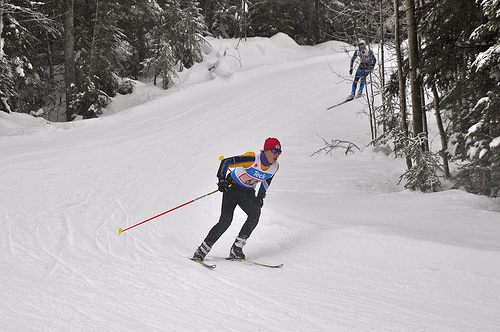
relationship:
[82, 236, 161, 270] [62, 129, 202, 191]
marks on snow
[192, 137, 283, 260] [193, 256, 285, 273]
man on skis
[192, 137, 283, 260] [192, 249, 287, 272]
man on skis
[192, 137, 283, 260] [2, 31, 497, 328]
man on snow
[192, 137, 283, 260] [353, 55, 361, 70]
man on ski pole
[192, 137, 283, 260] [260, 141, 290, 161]
man wearing sunglasses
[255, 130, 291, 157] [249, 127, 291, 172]
cap on head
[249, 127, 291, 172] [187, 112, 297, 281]
head of person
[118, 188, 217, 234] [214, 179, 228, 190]
pole in hand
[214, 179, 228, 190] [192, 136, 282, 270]
hand of person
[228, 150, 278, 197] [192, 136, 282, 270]
racing vest on person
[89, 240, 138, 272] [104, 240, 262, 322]
track in snow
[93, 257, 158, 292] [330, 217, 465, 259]
track in snow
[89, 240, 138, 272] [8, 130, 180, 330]
track in snow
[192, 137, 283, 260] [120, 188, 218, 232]
man holding pole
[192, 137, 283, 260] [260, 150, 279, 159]
man wearing goggles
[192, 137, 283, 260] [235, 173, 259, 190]
man wears number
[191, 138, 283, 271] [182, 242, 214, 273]
man wears skis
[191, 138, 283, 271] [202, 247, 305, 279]
man wears skis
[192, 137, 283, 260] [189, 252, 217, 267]
man wears ski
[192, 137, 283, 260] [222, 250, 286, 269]
man wears ski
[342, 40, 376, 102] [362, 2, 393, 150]
man through trees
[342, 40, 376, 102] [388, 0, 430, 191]
man through trees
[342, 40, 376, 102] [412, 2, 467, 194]
man through trees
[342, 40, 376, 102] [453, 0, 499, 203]
man through trees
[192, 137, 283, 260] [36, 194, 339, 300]
man on slope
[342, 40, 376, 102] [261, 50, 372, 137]
man on slope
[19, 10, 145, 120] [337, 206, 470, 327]
tree near ski trail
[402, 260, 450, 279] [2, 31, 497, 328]
track on snow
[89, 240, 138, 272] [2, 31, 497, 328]
track on snow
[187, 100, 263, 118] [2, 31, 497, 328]
track on snow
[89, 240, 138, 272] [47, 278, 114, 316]
track on snow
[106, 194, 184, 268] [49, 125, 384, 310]
track on snow